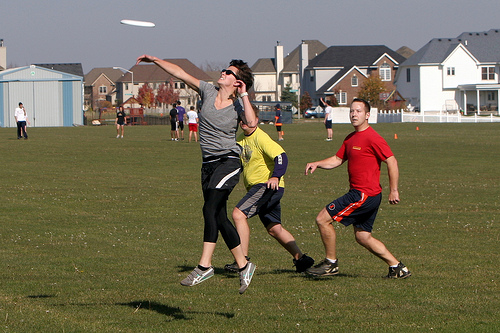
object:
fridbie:
[119, 18, 156, 28]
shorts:
[324, 188, 383, 233]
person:
[13, 102, 29, 140]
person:
[114, 106, 128, 140]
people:
[223, 102, 316, 273]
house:
[391, 28, 500, 117]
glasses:
[221, 68, 237, 79]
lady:
[135, 53, 258, 296]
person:
[169, 102, 180, 142]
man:
[303, 97, 412, 279]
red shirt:
[335, 125, 395, 198]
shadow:
[24, 292, 235, 323]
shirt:
[197, 80, 245, 159]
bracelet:
[240, 92, 249, 98]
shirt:
[14, 106, 29, 121]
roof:
[400, 28, 500, 66]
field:
[0, 115, 500, 333]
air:
[0, 0, 500, 333]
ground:
[0, 121, 500, 333]